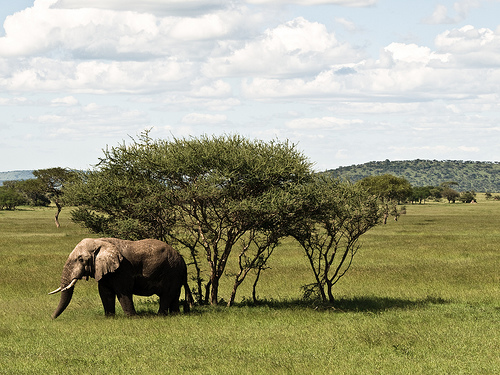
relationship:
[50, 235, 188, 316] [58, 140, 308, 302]
elephant stands next to tree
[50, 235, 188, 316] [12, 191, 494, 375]
elephant standing in wild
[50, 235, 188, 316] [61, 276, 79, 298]
elephant has tusk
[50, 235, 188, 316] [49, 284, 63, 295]
elephant has tusk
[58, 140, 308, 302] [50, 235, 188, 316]
tree next to elephant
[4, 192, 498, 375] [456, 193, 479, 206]
field has tree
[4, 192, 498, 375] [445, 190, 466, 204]
field has tree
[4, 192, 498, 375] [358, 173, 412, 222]
field has tree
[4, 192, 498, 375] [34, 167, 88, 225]
field has tree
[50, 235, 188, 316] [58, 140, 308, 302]
elephant standing under tree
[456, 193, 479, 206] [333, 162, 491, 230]
tree in distance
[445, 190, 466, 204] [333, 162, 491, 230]
tree in distance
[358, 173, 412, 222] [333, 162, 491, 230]
tree in distance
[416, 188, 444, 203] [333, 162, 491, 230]
tree in distance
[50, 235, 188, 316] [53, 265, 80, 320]
elephant has nose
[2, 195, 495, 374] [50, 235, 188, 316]
grass under elephant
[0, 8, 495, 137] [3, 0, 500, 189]
clouds are in sky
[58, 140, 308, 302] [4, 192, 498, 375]
tree in field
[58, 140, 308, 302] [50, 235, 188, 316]
tree behind elephant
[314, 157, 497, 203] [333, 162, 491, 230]
hill in distance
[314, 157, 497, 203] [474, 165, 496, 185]
hill covered by tree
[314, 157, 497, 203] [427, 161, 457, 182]
hill covered by tree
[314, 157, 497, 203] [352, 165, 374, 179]
hill covered by tree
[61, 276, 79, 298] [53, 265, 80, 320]
tusk on left of nose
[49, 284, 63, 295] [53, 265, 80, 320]
tusk on right of nose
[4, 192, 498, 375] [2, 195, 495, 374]
field full of grass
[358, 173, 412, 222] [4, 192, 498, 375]
tree in field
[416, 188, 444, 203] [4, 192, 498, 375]
tree in field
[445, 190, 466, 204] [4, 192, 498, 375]
tree in field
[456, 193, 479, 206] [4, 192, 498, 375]
tree in field